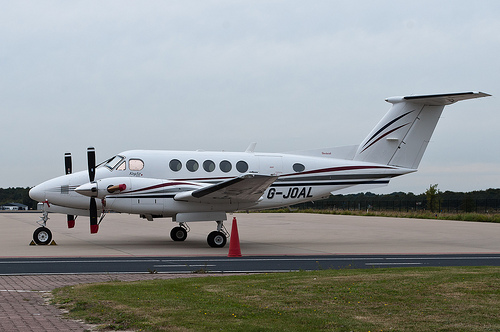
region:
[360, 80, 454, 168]
tail of the plane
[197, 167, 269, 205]
wing of the plane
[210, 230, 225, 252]
wheel of the plane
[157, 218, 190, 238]
wheel of the plane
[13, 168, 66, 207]
nose of the plane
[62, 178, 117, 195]
engine of the plane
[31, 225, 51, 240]
wheel of the plane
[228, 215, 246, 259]
cone on the ground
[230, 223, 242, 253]
the cone is orange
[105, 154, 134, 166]
windshield of the plane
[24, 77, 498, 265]
plane on a runway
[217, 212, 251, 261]
orange safety cone on road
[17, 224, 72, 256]
wheel of a plane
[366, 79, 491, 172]
tail of a plane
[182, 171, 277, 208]
left wing of a plane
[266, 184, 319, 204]
name on a plane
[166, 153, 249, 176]
circle windows on a plane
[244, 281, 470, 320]
green grass of an airport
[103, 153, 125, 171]
front windows of a cockpit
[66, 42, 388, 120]
blue sky in the distance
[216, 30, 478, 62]
long white cloud in sky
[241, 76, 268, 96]
blue shade in sky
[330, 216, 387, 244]
paved concrete slab for smooth landings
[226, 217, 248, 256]
orange cone on platform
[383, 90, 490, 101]
white horizontal stabilizer wing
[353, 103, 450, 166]
white vertical stabilizer wing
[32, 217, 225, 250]
landing and take off gear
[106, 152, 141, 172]
cockpit for pilot and copilot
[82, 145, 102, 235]
black and red propellers for flight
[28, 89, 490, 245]
Beechcraft King Air aircraft plane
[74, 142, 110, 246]
Propeller on a plane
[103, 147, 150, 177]
Windows on a plane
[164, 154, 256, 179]
Five round windows on a plane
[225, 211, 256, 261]
Orange cone by a plane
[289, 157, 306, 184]
Small window on a plane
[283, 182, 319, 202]
JOAL written on a plane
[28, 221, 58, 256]
tire on a plane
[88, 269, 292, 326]
grass by a runway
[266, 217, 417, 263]
Gray paved runway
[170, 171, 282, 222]
Wing on a plane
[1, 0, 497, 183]
the sky is gray.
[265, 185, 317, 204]
G-JOAL is on a white surface.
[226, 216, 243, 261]
A cone is orange.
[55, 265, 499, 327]
the grass is green and has light spots.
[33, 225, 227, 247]
three wheels are on the ground.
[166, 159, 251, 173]
Five windows are round.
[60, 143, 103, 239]
Two propellers are on a plane.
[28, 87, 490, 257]
A plane is mostly white.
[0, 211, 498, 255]
the tarmac is gray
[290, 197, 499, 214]
a fence is in the background